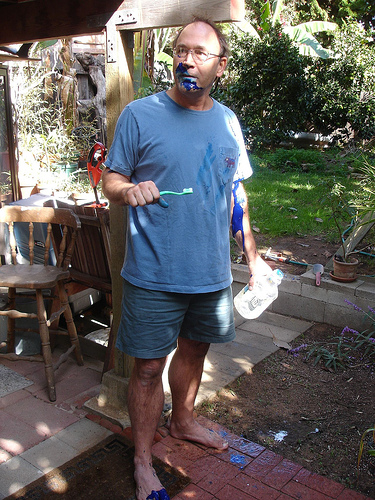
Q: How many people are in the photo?
A: One.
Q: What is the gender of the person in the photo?
A: Male.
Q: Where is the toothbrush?
A: In the man's right hand.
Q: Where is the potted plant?
A: On the stone ledge on the right side of the photo.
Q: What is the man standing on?
A: Bricks and a welcome mat.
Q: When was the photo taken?
A: During the day.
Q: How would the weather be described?
A: Sunny.